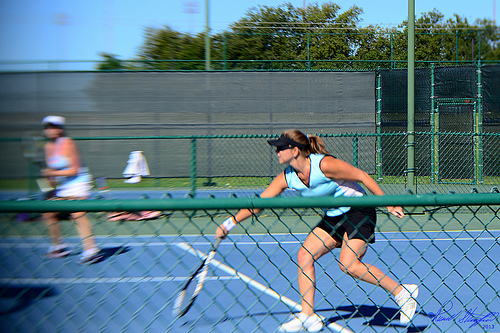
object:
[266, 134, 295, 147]
visor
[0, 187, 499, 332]
fence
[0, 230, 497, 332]
court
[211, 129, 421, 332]
woman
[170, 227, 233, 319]
racket